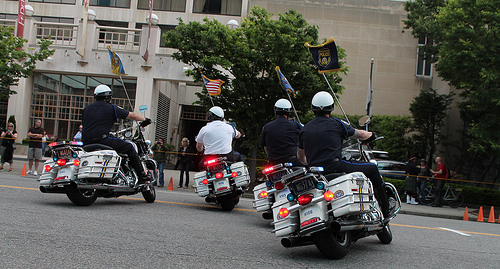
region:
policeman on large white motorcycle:
[40, 81, 164, 204]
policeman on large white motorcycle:
[275, 83, 401, 259]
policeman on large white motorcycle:
[248, 95, 313, 226]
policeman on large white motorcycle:
[187, 103, 257, 213]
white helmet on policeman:
[95, 85, 113, 102]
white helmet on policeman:
[204, 106, 226, 121]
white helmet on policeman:
[272, 96, 293, 109]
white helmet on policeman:
[309, 88, 341, 111]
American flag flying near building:
[199, 70, 224, 105]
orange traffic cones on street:
[457, 206, 499, 222]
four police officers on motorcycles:
[36, 61, 409, 258]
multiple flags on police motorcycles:
[100, 43, 380, 128]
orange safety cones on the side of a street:
[455, 204, 497, 225]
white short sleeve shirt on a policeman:
[187, 103, 244, 159]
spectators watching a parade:
[1, 112, 46, 177]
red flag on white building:
[6, 0, 41, 52]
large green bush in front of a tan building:
[165, 0, 354, 150]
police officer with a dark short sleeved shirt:
[294, 88, 363, 173]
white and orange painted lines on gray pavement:
[410, 213, 484, 246]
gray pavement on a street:
[7, 201, 208, 264]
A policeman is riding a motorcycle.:
[37, 83, 160, 205]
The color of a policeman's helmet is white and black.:
[91, 81, 111, 102]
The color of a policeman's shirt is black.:
[77, 98, 131, 139]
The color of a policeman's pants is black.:
[77, 133, 154, 187]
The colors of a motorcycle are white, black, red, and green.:
[34, 113, 163, 204]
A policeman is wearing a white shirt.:
[192, 118, 244, 155]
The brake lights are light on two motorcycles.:
[199, 155, 279, 177]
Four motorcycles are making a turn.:
[35, 84, 398, 261]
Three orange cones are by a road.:
[459, 198, 498, 225]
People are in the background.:
[0, 114, 463, 207]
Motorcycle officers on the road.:
[256, 83, 407, 257]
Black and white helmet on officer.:
[305, 90, 337, 119]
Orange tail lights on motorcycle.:
[272, 183, 338, 220]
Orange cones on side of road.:
[460, 203, 496, 225]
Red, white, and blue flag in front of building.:
[197, 67, 232, 106]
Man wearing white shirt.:
[190, 107, 250, 207]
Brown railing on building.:
[32, 20, 83, 47]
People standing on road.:
[4, 115, 46, 180]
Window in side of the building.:
[411, 21, 435, 83]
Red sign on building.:
[13, 0, 29, 44]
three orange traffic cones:
[458, 203, 497, 223]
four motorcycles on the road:
[37, 83, 402, 258]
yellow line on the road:
[1, 171, 498, 266]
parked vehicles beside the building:
[337, 148, 406, 185]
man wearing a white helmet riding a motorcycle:
[40, 83, 160, 202]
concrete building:
[0, 0, 499, 183]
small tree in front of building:
[407, 88, 454, 185]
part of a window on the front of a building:
[414, 30, 434, 80]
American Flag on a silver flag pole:
[197, 70, 225, 107]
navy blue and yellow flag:
[303, 40, 352, 126]